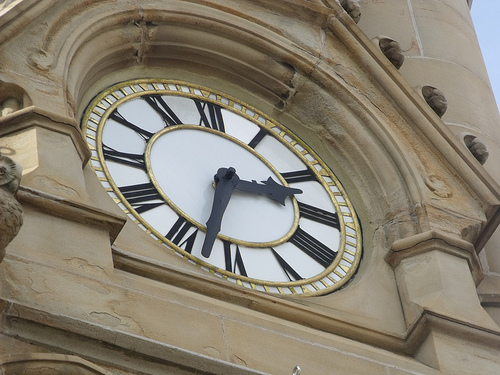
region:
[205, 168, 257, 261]
Black hand on clock.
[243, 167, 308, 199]
Black hand on clock.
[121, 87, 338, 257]
Clock is round in shape.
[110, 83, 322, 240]
Clock face is white.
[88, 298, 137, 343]
Chipped bock of stone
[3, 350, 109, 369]
A small stone arc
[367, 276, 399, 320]
Smooth clean brown wall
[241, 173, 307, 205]
Short arm of watch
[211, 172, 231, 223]
Long black arm clock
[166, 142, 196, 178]
Crisp white clock patch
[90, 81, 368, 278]
A big wall clock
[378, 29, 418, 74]
Dark brown stone pebbles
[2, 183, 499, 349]
A big stone building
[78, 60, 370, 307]
this is a clock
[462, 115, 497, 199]
this is a stone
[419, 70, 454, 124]
this is a stone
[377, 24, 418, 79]
this is a stone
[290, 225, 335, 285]
this is a number on the clock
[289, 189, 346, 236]
this is a number on the clock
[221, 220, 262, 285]
this is a number on the clock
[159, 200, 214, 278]
this is a number on the clock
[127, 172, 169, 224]
this is a number on the clock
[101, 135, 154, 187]
this is a number on the clock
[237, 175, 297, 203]
the black house hand on a clock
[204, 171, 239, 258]
the black minute hand on a clock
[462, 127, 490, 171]
a gray cement knob on a building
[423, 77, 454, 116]
a gray cement knob on a building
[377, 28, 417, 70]
a gray cement knob on a building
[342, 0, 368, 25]
a gray cement knob on a building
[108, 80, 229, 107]
gold filagree on a clock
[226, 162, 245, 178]
a black attachment pin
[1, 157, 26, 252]
a stone owl statue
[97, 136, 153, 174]
a roman numeral on the clock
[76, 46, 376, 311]
black and white clock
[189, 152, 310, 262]
black clock hands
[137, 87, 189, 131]
black roman numerals on face of clock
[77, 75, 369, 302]
gold circular design around black and white clock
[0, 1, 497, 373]
stone building with clock on front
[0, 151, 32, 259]
stone sculpture of owl beneath the clock on stone tower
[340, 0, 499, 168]
round stone sculptures on top of clock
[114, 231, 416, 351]
stone ledge underneath clock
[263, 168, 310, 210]
arrow on end of clock hand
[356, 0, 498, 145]
stone tile on surface of building